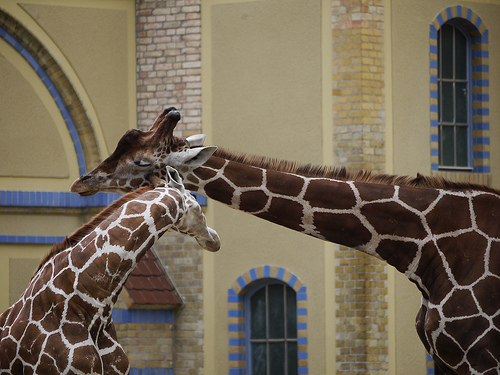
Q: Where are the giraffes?
A: In front of a building.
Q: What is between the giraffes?
A: A window.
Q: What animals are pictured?
A: Giraffes.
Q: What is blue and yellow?
A: The trim around the windows.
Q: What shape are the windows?
A: Arches.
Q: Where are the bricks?
A: On the wall.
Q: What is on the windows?
A: Bars.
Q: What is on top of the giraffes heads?
A: Horns.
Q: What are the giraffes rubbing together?
A: Heads.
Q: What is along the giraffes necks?
A: Hair.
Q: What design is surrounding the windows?
A: Stripes.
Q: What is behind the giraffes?
A: A building.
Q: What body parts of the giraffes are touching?
A: Heads.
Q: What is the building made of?
A: Concrete.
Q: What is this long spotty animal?
A: Giraffe.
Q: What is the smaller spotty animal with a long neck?
A: Giraffe.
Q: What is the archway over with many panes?
A: Window.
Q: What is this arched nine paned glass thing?
A: Window.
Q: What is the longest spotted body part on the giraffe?
A: Neck.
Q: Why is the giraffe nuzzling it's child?
A: Love.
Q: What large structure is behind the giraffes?
A: Building.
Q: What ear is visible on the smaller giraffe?
A: Right one.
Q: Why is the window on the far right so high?
A: So the giraffes can see through it.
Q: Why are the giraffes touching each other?
A: They like each other.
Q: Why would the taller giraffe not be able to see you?
A: Its eyes are closed.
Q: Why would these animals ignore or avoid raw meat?
A: They are herbivores.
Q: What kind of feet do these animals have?
A: Hooves.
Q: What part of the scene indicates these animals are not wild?
A: The building in the background.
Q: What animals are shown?
A: Giraffes.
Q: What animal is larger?
A: Right side.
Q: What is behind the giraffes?
A: Building.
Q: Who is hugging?
A: Giraffes.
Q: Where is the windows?
A: Between the giraffes.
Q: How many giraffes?
A: Two.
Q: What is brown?
A: Spots.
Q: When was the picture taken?
A: Daytime.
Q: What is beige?
A: Building.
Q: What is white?
A: Lines on giraffes.